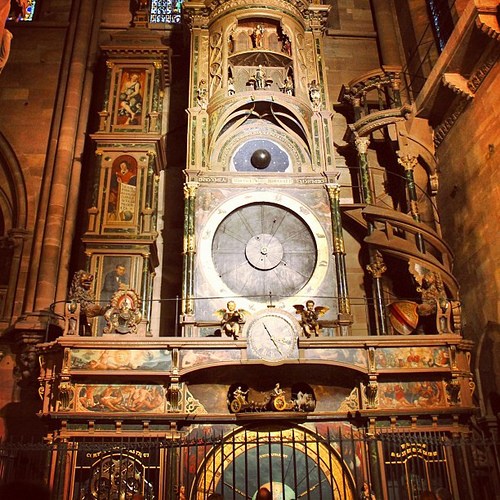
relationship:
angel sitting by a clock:
[276, 275, 353, 349] [210, 201, 326, 298]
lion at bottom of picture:
[64, 265, 105, 338] [89, 252, 136, 334]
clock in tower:
[245, 316, 305, 358] [179, 0, 351, 345]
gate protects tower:
[0, 422, 499, 500] [17, 4, 494, 495]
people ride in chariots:
[224, 380, 289, 397] [224, 395, 312, 411]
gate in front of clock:
[60, 401, 477, 498] [163, 174, 335, 326]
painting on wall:
[53, 47, 465, 466] [203, 160, 345, 315]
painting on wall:
[100, 150, 152, 237] [74, 49, 182, 328]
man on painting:
[107, 159, 139, 214] [100, 150, 152, 237]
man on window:
[102, 262, 132, 297] [83, 241, 143, 313]